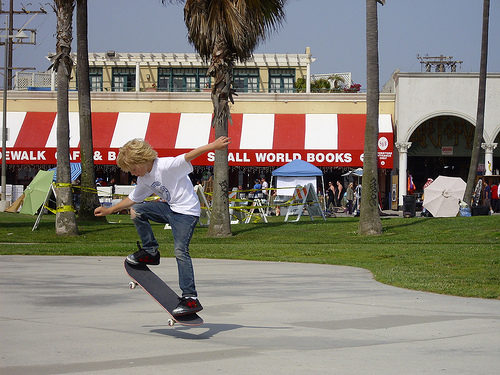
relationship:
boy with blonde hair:
[94, 135, 233, 317] [116, 137, 158, 177]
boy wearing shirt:
[87, 132, 234, 319] [126, 147, 202, 218]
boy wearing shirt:
[94, 135, 233, 317] [126, 152, 202, 218]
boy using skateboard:
[94, 135, 233, 317] [122, 255, 204, 327]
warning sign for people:
[282, 183, 327, 228] [320, 177, 355, 212]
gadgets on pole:
[0, 0, 47, 75] [333, 10, 413, 247]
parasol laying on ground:
[19, 170, 54, 216] [2, 196, 498, 373]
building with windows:
[90, 48, 312, 95] [91, 65, 291, 92]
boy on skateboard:
[94, 135, 233, 317] [122, 255, 204, 327]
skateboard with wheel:
[122, 255, 204, 327] [127, 280, 137, 290]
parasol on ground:
[19, 170, 54, 216] [2, 196, 498, 373]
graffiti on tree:
[369, 176, 379, 208] [355, 0, 386, 234]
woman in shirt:
[325, 180, 337, 210] [326, 190, 333, 199]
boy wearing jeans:
[94, 135, 233, 317] [126, 199, 201, 301]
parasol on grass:
[423, 173, 470, 217] [0, 220, 492, 298]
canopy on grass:
[264, 157, 330, 218] [3, 213, 499, 300]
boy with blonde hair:
[94, 135, 233, 317] [115, 137, 158, 173]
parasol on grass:
[18, 168, 53, 216] [3, 213, 499, 300]